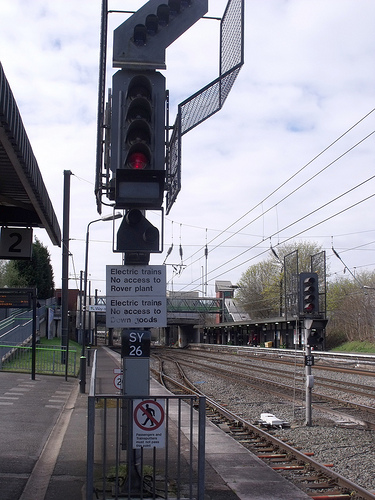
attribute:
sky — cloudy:
[0, 0, 374, 302]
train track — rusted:
[153, 338, 374, 499]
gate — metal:
[89, 394, 206, 499]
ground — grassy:
[6, 339, 88, 378]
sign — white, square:
[105, 265, 166, 328]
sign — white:
[0, 231, 34, 259]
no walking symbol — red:
[135, 401, 164, 431]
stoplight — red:
[128, 149, 149, 170]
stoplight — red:
[306, 302, 316, 313]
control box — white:
[261, 413, 293, 430]